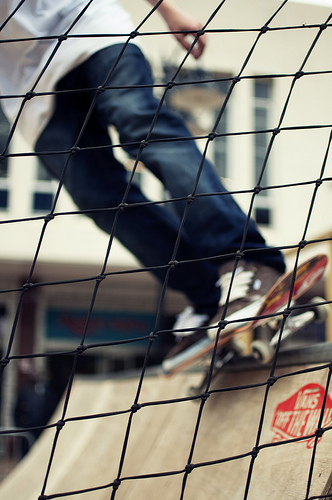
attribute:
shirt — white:
[3, 8, 159, 70]